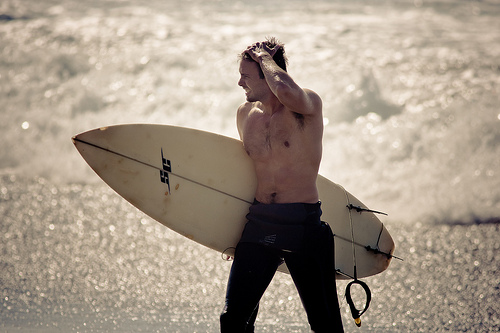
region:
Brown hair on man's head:
[237, 35, 294, 107]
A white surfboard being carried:
[66, 117, 395, 282]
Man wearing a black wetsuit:
[216, 34, 349, 331]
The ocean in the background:
[2, 1, 498, 229]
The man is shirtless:
[233, 36, 328, 204]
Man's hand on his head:
[237, 32, 296, 106]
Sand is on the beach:
[2, 171, 498, 329]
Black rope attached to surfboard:
[341, 275, 376, 329]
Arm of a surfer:
[244, 40, 325, 116]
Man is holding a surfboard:
[69, 36, 401, 330]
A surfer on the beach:
[1, 2, 499, 330]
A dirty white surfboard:
[64, 119, 398, 282]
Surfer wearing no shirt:
[229, 32, 329, 201]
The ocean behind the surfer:
[2, 0, 499, 233]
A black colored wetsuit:
[213, 194, 348, 331]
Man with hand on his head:
[232, 32, 332, 114]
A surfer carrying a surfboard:
[71, 32, 398, 331]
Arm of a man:
[247, 39, 324, 118]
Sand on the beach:
[2, 183, 499, 331]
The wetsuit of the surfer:
[213, 193, 348, 330]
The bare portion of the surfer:
[217, 34, 334, 204]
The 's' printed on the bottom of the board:
[154, 169, 181, 189]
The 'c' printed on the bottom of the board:
[155, 144, 182, 174]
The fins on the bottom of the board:
[336, 200, 408, 285]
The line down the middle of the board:
[72, 135, 369, 249]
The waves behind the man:
[4, 3, 498, 225]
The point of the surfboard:
[65, 124, 89, 155]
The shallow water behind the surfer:
[3, 224, 498, 331]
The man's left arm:
[247, 36, 324, 119]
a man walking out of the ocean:
[221, 38, 340, 331]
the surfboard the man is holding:
[70, 107, 405, 283]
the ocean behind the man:
[5, 3, 497, 223]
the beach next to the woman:
[0, 209, 499, 331]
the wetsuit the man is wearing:
[210, 198, 349, 332]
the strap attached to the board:
[335, 271, 375, 325]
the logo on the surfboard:
[146, 143, 176, 195]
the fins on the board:
[341, 202, 400, 275]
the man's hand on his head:
[245, 40, 279, 67]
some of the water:
[26, 50, 181, 107]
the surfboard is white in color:
[55, 113, 401, 293]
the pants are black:
[242, 203, 344, 331]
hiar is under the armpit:
[292, 109, 309, 128]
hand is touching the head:
[241, 28, 331, 133]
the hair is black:
[258, 35, 295, 75]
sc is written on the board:
[154, 153, 184, 199]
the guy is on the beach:
[46, 45, 443, 328]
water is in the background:
[333, 32, 492, 174]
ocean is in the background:
[47, 14, 495, 29]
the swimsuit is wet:
[228, 205, 348, 331]